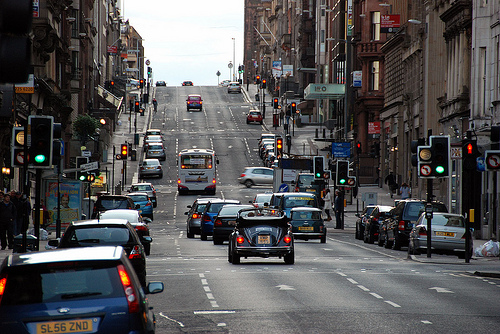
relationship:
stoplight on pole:
[25, 114, 55, 166] [27, 168, 51, 248]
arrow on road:
[260, 282, 308, 301] [164, 254, 491, 334]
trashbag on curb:
[475, 241, 497, 257] [455, 243, 496, 270]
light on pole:
[409, 150, 435, 179] [417, 168, 445, 258]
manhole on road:
[178, 297, 223, 330] [164, 254, 491, 334]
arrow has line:
[260, 282, 308, 301] [190, 306, 231, 319]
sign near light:
[410, 162, 439, 179] [409, 150, 435, 179]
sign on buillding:
[363, 116, 388, 144] [374, 22, 421, 188]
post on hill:
[216, 29, 249, 81] [157, 82, 266, 182]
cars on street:
[139, 132, 273, 191] [156, 87, 292, 300]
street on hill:
[156, 87, 292, 300] [157, 82, 266, 182]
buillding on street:
[374, 22, 421, 188] [156, 87, 292, 300]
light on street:
[409, 150, 435, 179] [156, 87, 292, 300]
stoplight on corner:
[25, 114, 55, 166] [6, 172, 58, 254]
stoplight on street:
[25, 114, 55, 166] [156, 87, 292, 300]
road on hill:
[164, 254, 491, 334] [157, 82, 266, 182]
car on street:
[231, 186, 294, 262] [156, 87, 292, 300]